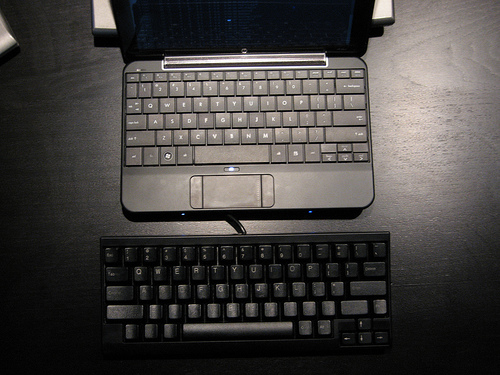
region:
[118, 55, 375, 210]
a gray laptop keyboard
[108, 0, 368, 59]
a black laptop screen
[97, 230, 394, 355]
a black computer keyboard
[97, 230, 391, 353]
a full size keyboard plugged into the laptop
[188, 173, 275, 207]
a trackpad on the laptop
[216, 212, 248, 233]
a cord connecting the keyboard to the laptop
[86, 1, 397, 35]
a metal object behind the laptop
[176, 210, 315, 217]
two blue lights on the front of the laptop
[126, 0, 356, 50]
blue text on the laptop screen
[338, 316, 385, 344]
arrow keys on the keyboard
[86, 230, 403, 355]
Black keyboard on a desk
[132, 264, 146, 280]
Black key with white lettering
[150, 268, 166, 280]
Black key with white lettering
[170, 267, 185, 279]
Black key with white lettering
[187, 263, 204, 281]
Black key with white lettering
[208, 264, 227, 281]
Black key with white lettering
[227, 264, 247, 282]
Black key with white lettering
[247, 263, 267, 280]
Black key with white lettering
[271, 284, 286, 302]
Black key with white lettering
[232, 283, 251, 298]
Black key with white lettering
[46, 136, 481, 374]
a black computer keyboard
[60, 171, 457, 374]
a black keyboard on a table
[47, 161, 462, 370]
a black computer keyboard on a table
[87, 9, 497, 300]
a netbook on a table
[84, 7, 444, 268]
a black netbook on a table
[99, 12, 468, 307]
a black netbook on black table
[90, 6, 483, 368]
a small laptop computer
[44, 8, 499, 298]
a small laptop on a table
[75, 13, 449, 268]
a small laptop on a black table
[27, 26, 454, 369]
a netbook and keyboard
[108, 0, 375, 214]
the opened laptop on the flat surface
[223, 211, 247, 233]
the wire between the laptop and the keyboard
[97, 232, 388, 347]
the keyboard separate from the laptop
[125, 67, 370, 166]
the keyboard on the laptop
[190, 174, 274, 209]
the trackpad on the laptop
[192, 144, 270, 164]
the space bar on the laptop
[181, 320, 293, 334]
the space bar on the keyboard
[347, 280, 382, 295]
the enter key on the keyboard separate from the laptop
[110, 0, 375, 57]
the screen on the laptop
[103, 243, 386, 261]
the first row of keys on the keyboard separate from the laptop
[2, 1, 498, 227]
Open Laptop Computer Sitting on Tabletop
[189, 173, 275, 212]
Laptop Mousepad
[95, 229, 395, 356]
Laptop Computer External Keyboard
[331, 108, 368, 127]
Laptop Enter Return Key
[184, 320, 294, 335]
External Laptop Keyboard Spacebar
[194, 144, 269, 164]
Laptop Computer Spacebar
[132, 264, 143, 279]
External Laptop Keyboard Q Key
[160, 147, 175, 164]
Laptop Computer Windows Key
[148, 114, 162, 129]
Laptop Computer A Key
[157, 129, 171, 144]
Laptop Computer Z Key